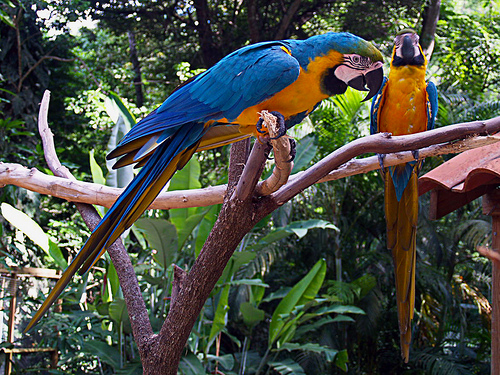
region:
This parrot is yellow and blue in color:
[400, 32, 452, 374]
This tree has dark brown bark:
[195, 240, 212, 307]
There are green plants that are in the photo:
[258, 263, 307, 307]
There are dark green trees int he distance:
[113, 25, 150, 79]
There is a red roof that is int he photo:
[448, 144, 484, 201]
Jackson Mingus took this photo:
[58, 6, 441, 345]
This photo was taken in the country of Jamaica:
[123, 43, 395, 373]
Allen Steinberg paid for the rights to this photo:
[98, 32, 425, 372]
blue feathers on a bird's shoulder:
[222, 52, 293, 100]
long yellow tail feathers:
[385, 195, 446, 374]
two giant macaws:
[84, 21, 451, 353]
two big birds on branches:
[37, 1, 466, 374]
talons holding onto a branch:
[248, 108, 301, 175]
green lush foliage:
[264, 249, 368, 374]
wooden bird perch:
[197, 164, 279, 253]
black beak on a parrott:
[358, 66, 380, 111]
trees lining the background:
[80, 17, 179, 84]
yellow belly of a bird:
[392, 73, 424, 130]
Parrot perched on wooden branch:
[10, 28, 390, 335]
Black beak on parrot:
[346, 68, 387, 105]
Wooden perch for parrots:
[7, 89, 498, 220]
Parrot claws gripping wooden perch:
[252, 108, 299, 168]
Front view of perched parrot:
[364, 25, 440, 367]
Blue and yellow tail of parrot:
[17, 127, 212, 344]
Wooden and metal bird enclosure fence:
[3, 264, 84, 374]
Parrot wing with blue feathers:
[106, 37, 300, 158]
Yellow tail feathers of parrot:
[378, 171, 429, 364]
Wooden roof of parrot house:
[421, 140, 498, 225]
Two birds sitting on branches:
[36, 25, 440, 358]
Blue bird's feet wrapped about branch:
[255, 108, 295, 163]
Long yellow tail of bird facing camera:
[376, 165, 423, 362]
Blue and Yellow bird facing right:
[18, 30, 384, 340]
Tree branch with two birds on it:
[0, 86, 495, 371]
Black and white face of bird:
[335, 30, 385, 100]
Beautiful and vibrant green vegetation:
[0, 0, 495, 371]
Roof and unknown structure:
[415, 120, 496, 371]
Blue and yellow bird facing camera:
[370, 26, 435, 361]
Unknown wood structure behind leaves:
[1, 253, 107, 374]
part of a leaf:
[311, 278, 333, 295]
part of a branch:
[196, 298, 201, 307]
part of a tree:
[206, 233, 216, 255]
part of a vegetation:
[326, 253, 351, 282]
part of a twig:
[366, 147, 381, 166]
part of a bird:
[136, 205, 144, 219]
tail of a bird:
[118, 180, 126, 194]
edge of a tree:
[161, 331, 183, 358]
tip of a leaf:
[308, 263, 318, 280]